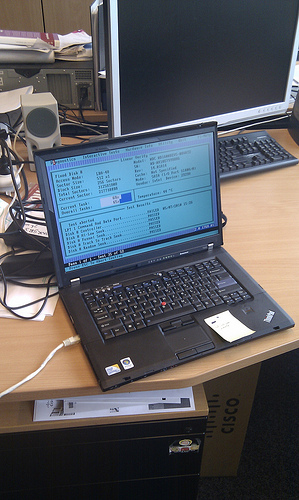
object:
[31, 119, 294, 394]
computer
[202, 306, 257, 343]
post it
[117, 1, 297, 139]
monitor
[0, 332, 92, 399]
cable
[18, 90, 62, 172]
speaker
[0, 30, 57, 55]
textbook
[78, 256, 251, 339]
keyboard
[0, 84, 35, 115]
papers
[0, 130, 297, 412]
desk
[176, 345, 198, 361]
button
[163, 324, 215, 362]
mouse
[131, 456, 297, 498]
floor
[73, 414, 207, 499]
cabinet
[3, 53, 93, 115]
tower